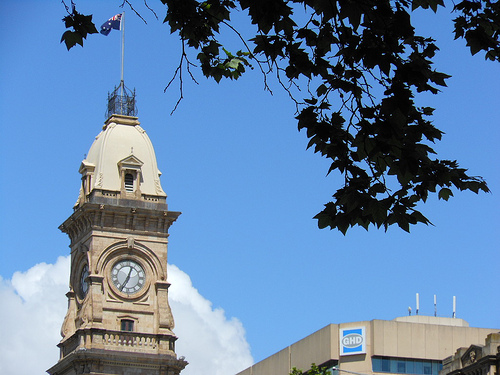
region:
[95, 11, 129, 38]
small flag above clock tower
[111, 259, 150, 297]
white clock face on tower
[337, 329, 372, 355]
blue and white ghd sign on building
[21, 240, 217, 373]
white cumulus cloud in sky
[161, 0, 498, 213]
dark underside of leaves in foreground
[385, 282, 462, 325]
radio antanas on building top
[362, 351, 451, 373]
blue glass panes on building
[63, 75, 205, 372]
Victorian style clock tower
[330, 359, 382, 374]
top of street light near building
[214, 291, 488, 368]
large modern style building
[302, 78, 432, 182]
leaves on tree branches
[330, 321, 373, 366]
sign on building corner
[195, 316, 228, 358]
white could in sky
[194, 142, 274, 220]
blue of daytime sky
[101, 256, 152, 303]
clock face on tower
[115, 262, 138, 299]
two black hands of clock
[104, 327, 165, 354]
balcony on clock tower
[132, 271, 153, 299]
roman numerals on clock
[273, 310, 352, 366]
flat roof of building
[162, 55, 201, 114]
twigs on tree branch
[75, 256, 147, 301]
clocks on tower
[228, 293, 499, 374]
concrete building with antenna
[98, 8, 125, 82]
flag on top of clock tower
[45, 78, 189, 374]
ornate building tower made of concrete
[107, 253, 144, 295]
numerals on clock are roman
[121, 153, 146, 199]
small window on tower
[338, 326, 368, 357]
sign on building says GHD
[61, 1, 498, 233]
leaves on tree are green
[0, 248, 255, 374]
cloud is white and fluffy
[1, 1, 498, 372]
the sky is blue with one cloud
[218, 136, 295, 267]
this is the sky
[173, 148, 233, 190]
the sky is blue in color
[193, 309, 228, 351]
this is the cloud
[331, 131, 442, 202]
this is a tree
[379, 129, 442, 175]
the leaves are green in color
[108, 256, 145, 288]
this is a clock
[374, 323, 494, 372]
this is a building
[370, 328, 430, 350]
this is the wall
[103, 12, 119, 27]
this is a flag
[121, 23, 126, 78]
this is the pole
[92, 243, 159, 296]
clock on a tower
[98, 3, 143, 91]
flag on top of tower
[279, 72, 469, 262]
green leaves of a tree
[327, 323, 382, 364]
sign on a building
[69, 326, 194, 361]
balcony on a tower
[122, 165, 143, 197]
window on a tower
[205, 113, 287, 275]
clear blue sky in the distance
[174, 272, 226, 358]
white clouds in the sky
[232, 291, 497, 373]
building to the side of tower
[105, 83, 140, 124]
black decoration on top of tower